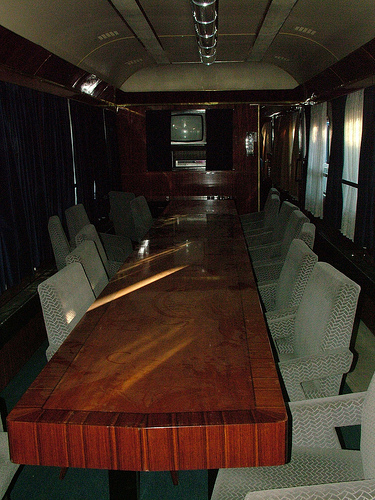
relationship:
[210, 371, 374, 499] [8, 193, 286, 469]
chair next to table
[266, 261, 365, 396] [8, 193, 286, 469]
chair next to table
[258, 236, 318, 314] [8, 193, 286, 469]
chair next to table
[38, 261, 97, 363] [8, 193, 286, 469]
chair next to table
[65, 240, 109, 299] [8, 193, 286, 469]
chair next to table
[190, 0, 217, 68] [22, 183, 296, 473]
lighting above desk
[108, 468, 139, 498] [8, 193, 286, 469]
leg for table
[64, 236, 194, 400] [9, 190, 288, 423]
reflection on tabletop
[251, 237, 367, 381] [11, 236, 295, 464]
chairs lining table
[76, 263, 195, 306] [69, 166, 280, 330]
reflection on table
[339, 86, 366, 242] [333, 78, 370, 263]
curtains on window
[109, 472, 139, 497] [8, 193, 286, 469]
leg supporting table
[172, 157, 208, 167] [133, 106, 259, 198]
device in stand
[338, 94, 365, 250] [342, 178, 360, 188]
cross beam on window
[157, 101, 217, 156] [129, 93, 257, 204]
television in wall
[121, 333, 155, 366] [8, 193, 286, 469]
dust on table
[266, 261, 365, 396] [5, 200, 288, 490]
chair around table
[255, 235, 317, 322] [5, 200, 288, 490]
chair around table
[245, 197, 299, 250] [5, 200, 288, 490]
chair around table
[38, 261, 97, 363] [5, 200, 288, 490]
chair around table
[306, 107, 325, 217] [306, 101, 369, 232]
curtains on windows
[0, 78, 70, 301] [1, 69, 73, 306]
curtain on window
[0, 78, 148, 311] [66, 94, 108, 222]
curtain on window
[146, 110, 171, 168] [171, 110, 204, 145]
curtains cover television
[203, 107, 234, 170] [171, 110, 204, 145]
curtains cover television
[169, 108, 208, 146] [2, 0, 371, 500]
television in train car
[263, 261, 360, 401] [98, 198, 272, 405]
chair at table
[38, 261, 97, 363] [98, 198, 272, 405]
chair at table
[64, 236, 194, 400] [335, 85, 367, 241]
reflection comes through window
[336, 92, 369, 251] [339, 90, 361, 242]
window has curtain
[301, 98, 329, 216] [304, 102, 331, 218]
window has curtain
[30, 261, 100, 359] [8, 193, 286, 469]
chair under table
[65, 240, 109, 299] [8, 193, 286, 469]
chair under table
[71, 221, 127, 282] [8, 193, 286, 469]
chair under table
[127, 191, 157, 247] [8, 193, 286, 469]
chair under table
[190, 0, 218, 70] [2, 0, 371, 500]
lighting in train car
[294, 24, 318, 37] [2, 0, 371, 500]
vents in train car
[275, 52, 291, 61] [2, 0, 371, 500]
vents in train car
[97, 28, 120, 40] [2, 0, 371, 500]
vents in train car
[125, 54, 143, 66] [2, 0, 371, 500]
vents in train car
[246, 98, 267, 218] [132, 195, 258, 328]
pole in front of table